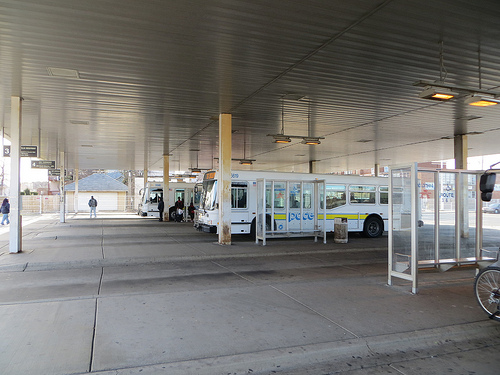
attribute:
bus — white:
[199, 170, 424, 243]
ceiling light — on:
[467, 94, 499, 109]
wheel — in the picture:
[474, 268, 498, 325]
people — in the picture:
[157, 192, 200, 225]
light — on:
[428, 89, 452, 105]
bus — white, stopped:
[195, 169, 424, 252]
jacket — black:
[0, 202, 10, 214]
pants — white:
[88, 205, 102, 217]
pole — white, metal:
[3, 84, 33, 251]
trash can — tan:
[324, 211, 352, 247]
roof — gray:
[66, 175, 141, 196]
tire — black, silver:
[463, 264, 496, 301]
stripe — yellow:
[266, 210, 372, 224]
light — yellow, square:
[269, 132, 293, 152]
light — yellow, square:
[297, 134, 322, 152]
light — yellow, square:
[417, 83, 457, 106]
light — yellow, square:
[232, 156, 260, 172]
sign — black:
[29, 157, 61, 173]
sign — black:
[2, 141, 42, 161]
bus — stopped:
[134, 169, 198, 222]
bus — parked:
[191, 166, 426, 247]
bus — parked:
[131, 176, 205, 227]